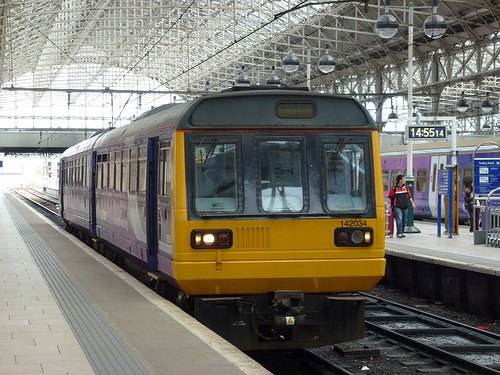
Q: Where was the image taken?
A: It was taken at the train station.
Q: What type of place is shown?
A: It is a train station.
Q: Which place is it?
A: It is a train station.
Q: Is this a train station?
A: Yes, it is a train station.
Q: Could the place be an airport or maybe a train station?
A: It is a train station.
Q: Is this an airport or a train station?
A: It is a train station.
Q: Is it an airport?
A: No, it is a train station.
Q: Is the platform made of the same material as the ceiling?
A: No, the platform is made of cement and the ceiling is made of metal.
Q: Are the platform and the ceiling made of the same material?
A: No, the platform is made of cement and the ceiling is made of metal.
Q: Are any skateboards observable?
A: No, there are no skateboards.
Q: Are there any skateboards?
A: No, there are no skateboards.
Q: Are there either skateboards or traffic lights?
A: No, there are no skateboards or traffic lights.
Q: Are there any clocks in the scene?
A: Yes, there is a clock.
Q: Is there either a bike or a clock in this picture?
A: Yes, there is a clock.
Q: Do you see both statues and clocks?
A: No, there is a clock but no statues.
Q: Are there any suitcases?
A: No, there are no suitcases.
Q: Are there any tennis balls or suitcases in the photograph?
A: No, there are no suitcases or tennis balls.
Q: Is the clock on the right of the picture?
A: Yes, the clock is on the right of the image.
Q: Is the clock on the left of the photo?
A: No, the clock is on the right of the image.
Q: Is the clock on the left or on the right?
A: The clock is on the right of the image.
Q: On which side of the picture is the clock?
A: The clock is on the right of the image.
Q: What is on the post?
A: The clock is on the post.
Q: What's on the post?
A: The clock is on the post.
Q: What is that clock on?
A: The clock is on the post.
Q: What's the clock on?
A: The clock is on the post.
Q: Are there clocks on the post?
A: Yes, there is a clock on the post.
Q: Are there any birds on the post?
A: No, there is a clock on the post.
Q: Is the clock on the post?
A: Yes, the clock is on the post.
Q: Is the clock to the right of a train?
A: Yes, the clock is to the right of a train.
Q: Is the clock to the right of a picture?
A: No, the clock is to the right of a train.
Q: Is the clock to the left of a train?
A: No, the clock is to the right of a train.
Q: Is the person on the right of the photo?
A: Yes, the person is on the right of the image.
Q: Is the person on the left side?
A: No, the person is on the right of the image.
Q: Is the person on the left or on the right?
A: The person is on the right of the image.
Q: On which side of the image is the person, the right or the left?
A: The person is on the right of the image.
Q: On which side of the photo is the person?
A: The person is on the right of the image.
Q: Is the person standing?
A: Yes, the person is standing.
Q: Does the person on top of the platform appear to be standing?
A: Yes, the person is standing.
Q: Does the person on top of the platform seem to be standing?
A: Yes, the person is standing.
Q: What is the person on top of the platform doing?
A: The person is standing.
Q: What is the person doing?
A: The person is standing.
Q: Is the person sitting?
A: No, the person is standing.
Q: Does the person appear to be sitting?
A: No, the person is standing.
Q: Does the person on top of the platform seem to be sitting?
A: No, the person is standing.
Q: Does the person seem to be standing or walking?
A: The person is standing.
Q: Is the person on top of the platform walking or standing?
A: The person is standing.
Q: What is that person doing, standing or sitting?
A: The person is standing.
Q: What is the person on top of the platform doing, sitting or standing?
A: The person is standing.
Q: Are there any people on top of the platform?
A: Yes, there is a person on top of the platform.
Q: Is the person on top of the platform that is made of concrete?
A: Yes, the person is on top of the platform.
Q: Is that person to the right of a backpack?
A: No, the person is to the right of the train.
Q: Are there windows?
A: Yes, there is a window.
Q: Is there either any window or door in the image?
A: Yes, there is a window.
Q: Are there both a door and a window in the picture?
A: Yes, there are both a window and a door.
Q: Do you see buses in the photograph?
A: No, there are no buses.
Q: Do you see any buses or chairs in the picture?
A: No, there are no buses or chairs.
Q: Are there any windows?
A: Yes, there is a window.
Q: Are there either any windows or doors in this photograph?
A: Yes, there is a window.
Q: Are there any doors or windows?
A: Yes, there is a window.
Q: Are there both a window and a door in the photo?
A: Yes, there are both a window and a door.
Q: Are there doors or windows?
A: Yes, there is a window.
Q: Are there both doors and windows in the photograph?
A: Yes, there are both a window and a door.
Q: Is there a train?
A: Yes, there is a train.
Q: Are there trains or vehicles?
A: Yes, there is a train.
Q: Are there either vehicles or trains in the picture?
A: Yes, there is a train.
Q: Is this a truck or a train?
A: This is a train.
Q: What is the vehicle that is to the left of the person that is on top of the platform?
A: The vehicle is a train.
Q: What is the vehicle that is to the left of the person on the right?
A: The vehicle is a train.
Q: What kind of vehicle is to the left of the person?
A: The vehicle is a train.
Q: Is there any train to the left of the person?
A: Yes, there is a train to the left of the person.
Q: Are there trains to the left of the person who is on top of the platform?
A: Yes, there is a train to the left of the person.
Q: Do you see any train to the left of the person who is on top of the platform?
A: Yes, there is a train to the left of the person.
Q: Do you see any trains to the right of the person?
A: No, the train is to the left of the person.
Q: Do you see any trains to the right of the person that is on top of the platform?
A: No, the train is to the left of the person.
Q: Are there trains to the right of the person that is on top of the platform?
A: No, the train is to the left of the person.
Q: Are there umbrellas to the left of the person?
A: No, there is a train to the left of the person.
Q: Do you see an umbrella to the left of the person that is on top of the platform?
A: No, there is a train to the left of the person.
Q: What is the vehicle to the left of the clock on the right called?
A: The vehicle is a train.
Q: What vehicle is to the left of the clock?
A: The vehicle is a train.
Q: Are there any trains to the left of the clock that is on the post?
A: Yes, there is a train to the left of the clock.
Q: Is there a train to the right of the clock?
A: No, the train is to the left of the clock.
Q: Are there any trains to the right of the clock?
A: No, the train is to the left of the clock.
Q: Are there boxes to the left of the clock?
A: No, there is a train to the left of the clock.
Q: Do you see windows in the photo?
A: Yes, there are windows.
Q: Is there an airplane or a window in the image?
A: Yes, there are windows.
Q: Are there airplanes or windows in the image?
A: Yes, there are windows.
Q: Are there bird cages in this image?
A: No, there are no bird cages.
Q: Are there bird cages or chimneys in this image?
A: No, there are no bird cages or chimneys.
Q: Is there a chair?
A: No, there are no chairs.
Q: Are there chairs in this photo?
A: No, there are no chairs.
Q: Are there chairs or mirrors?
A: No, there are no chairs or mirrors.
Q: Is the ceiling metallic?
A: Yes, the ceiling is metallic.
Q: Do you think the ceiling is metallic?
A: Yes, the ceiling is metallic.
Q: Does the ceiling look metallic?
A: Yes, the ceiling is metallic.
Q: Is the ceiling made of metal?
A: Yes, the ceiling is made of metal.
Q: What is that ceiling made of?
A: The ceiling is made of metal.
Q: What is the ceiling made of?
A: The ceiling is made of metal.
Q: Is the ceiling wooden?
A: No, the ceiling is metallic.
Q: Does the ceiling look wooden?
A: No, the ceiling is metallic.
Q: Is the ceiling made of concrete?
A: No, the ceiling is made of metal.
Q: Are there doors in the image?
A: Yes, there is a door.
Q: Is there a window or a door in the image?
A: Yes, there is a door.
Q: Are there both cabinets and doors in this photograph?
A: No, there is a door but no cabinets.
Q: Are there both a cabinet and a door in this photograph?
A: No, there is a door but no cabinets.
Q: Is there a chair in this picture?
A: No, there are no chairs.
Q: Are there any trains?
A: Yes, there is a train.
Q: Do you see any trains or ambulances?
A: Yes, there is a train.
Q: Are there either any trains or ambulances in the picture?
A: Yes, there is a train.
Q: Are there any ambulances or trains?
A: Yes, there is a train.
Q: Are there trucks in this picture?
A: No, there are no trucks.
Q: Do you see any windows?
A: Yes, there are windows.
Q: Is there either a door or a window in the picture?
A: Yes, there are windows.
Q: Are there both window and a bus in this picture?
A: No, there are windows but no buses.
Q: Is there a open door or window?
A: Yes, there are open windows.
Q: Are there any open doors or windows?
A: Yes, there are open windows.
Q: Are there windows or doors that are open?
A: Yes, the windows are open.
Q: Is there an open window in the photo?
A: Yes, there are open windows.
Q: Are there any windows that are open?
A: Yes, there are windows that are open.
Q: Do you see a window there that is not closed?
A: Yes, there are open windows.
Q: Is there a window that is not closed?
A: Yes, there are open windows.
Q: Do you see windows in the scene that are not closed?
A: Yes, there are open windows.